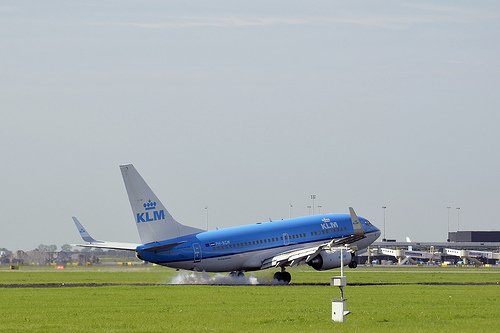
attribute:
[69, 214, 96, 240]
tip — upturned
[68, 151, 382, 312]
airplane — blue, white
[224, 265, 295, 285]
landing gears — down position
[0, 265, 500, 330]
grass — green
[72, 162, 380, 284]
airplane — white, blue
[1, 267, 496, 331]
field — large, grassy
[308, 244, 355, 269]
jet engine — under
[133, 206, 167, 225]
letters — blue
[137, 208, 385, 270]
body — blue, white